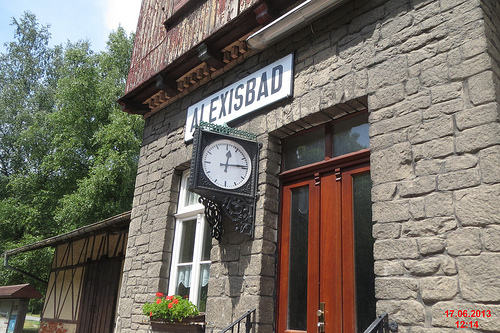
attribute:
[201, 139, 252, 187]
clock — metal, white, ornate, black, decorative, mounted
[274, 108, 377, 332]
door — red, wooden, glass, brown, closed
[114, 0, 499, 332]
building — grey, stone, gray, older, messy, rough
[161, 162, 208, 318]
window — white, closed, wood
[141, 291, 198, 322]
flowers — red, green, growing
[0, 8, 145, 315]
trees — leafy, green, tall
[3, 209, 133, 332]
building — wooden, tan, brown, small, tudor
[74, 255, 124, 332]
door — wooden, brown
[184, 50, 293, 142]
sign — white, black, rectangular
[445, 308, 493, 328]
stamp — red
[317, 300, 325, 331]
doorknob — brass, metal, silver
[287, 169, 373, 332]
windows — long, glass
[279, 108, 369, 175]
windows — small, glass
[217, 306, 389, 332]
railings — black, iron, metal, attached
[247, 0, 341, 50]
light — mounted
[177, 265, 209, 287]
curtains — white